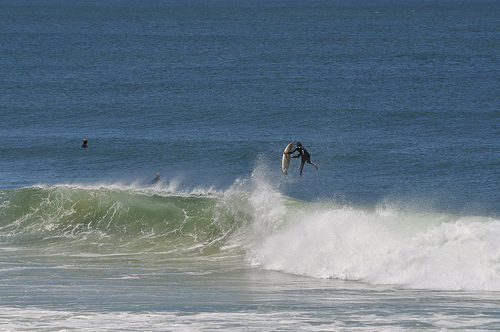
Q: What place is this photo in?
A: It is at the ocean.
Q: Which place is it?
A: It is an ocean.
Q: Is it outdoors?
A: Yes, it is outdoors.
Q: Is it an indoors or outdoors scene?
A: It is outdoors.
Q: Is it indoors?
A: No, it is outdoors.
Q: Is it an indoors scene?
A: No, it is outdoors.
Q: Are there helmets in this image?
A: No, there are no helmets.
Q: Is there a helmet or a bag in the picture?
A: No, there are no helmets or bags.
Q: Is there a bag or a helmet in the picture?
A: No, there are no helmets or bags.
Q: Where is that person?
A: The person is in the sky.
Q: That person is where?
A: The person is in the sky.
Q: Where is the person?
A: The person is in the sky.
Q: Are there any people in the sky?
A: Yes, there is a person in the sky.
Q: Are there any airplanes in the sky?
A: No, there is a person in the sky.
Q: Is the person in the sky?
A: Yes, the person is in the sky.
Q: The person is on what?
A: The person is on the surf board.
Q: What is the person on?
A: The person is on the surf board.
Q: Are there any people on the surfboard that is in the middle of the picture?
A: Yes, there is a person on the surfboard.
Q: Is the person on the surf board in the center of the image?
A: Yes, the person is on the surfboard.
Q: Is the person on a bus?
A: No, the person is on the surfboard.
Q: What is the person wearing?
A: The person is wearing a wetsuit.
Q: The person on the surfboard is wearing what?
A: The person is wearing a wetsuit.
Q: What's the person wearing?
A: The person is wearing a wetsuit.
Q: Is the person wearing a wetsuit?
A: Yes, the person is wearing a wetsuit.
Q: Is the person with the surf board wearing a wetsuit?
A: Yes, the person is wearing a wetsuit.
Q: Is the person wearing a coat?
A: No, the person is wearing a wetsuit.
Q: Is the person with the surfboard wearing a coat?
A: No, the person is wearing a wetsuit.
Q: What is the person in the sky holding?
A: The person is holding the surf board.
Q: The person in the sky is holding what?
A: The person is holding the surf board.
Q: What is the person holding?
A: The person is holding the surf board.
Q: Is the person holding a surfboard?
A: Yes, the person is holding a surfboard.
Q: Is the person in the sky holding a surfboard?
A: Yes, the person is holding a surfboard.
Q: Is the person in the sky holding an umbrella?
A: No, the person is holding a surfboard.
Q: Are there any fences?
A: No, there are no fences.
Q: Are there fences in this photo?
A: No, there are no fences.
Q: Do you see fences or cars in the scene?
A: No, there are no fences or cars.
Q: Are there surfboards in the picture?
A: Yes, there is a surfboard.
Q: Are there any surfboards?
A: Yes, there is a surfboard.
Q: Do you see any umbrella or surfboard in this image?
A: Yes, there is a surfboard.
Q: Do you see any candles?
A: No, there are no candles.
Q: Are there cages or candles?
A: No, there are no candles or cages.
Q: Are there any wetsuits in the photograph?
A: Yes, there is a wetsuit.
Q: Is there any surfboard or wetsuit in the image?
A: Yes, there is a wetsuit.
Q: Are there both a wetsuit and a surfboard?
A: Yes, there are both a wetsuit and a surfboard.